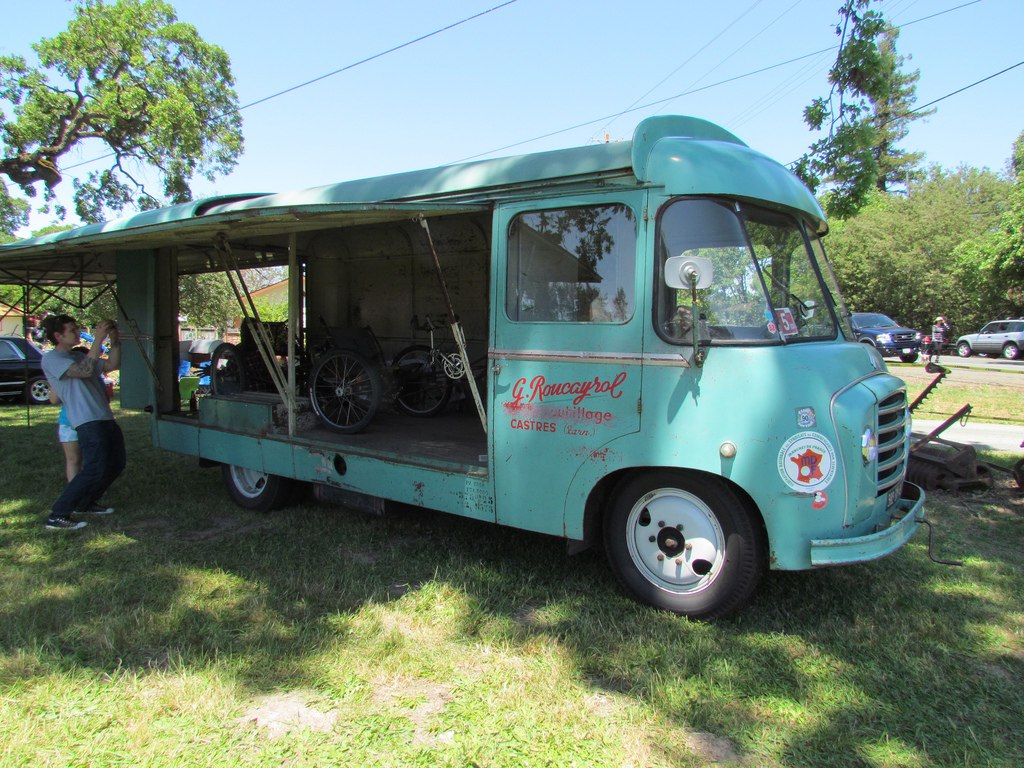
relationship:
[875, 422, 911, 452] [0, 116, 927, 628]
slat on truck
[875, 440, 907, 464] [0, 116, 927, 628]
slat on truck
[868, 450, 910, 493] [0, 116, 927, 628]
slat on truck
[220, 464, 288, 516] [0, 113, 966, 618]
wheel belongs to truck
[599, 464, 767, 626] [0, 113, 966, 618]
wheel belongs to truck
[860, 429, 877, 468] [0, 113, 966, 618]
headlight belongs to truck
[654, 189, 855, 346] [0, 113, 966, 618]
windshield belongs to truck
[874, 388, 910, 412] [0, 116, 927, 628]
slat on truck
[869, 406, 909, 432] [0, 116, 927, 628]
slat on truck